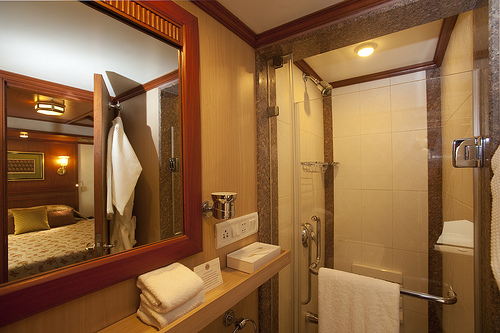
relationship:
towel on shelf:
[138, 260, 207, 313] [94, 242, 291, 332]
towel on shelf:
[136, 262, 206, 331] [94, 242, 291, 332]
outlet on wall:
[212, 206, 260, 248] [197, 17, 259, 257]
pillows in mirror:
[9, 193, 77, 240] [0, 0, 182, 285]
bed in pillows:
[7, 193, 129, 288] [9, 193, 77, 240]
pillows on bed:
[9, 193, 77, 240] [7, 193, 129, 288]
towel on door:
[105, 116, 142, 253] [86, 73, 116, 255]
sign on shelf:
[194, 255, 224, 290] [177, 270, 262, 308]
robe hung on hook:
[105, 110, 155, 261] [108, 97, 120, 112]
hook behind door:
[108, 97, 120, 112] [91, 67, 120, 258]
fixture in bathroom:
[347, 39, 384, 64] [5, 6, 478, 325]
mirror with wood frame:
[1, 0, 203, 325] [0, 3, 211, 245]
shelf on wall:
[94, 242, 291, 332] [212, 53, 249, 177]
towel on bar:
[301, 253, 418, 331] [305, 260, 456, 310]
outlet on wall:
[214, 212, 258, 250] [5, 4, 259, 329]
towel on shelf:
[136, 262, 206, 331] [85, 233, 291, 331]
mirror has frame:
[1, 0, 203, 325] [182, 16, 204, 254]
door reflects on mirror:
[86, 73, 116, 255] [1, 0, 203, 325]